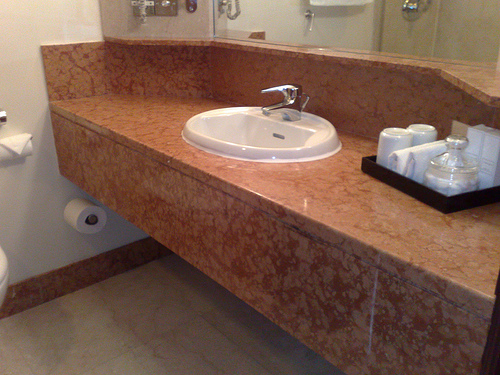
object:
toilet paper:
[0, 132, 33, 162]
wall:
[0, 0, 149, 287]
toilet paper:
[63, 197, 107, 235]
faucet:
[259, 84, 311, 123]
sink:
[182, 106, 343, 161]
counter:
[49, 97, 499, 320]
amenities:
[361, 118, 499, 214]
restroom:
[0, 0, 499, 374]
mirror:
[99, 1, 499, 65]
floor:
[1, 252, 344, 375]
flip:
[2, 134, 32, 158]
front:
[48, 111, 499, 374]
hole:
[272, 132, 284, 140]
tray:
[360, 154, 499, 215]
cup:
[406, 123, 437, 146]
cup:
[376, 128, 413, 169]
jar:
[424, 134, 483, 195]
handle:
[87, 215, 96, 224]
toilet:
[0, 249, 12, 308]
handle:
[260, 83, 301, 95]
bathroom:
[18, 0, 491, 371]